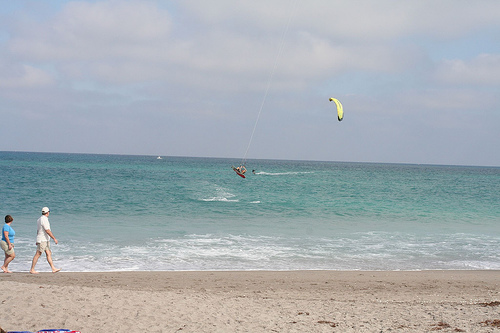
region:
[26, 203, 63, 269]
Man walking on the beach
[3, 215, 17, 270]
Woman walking on the beach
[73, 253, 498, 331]
Sand on a beach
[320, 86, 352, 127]
Kite in the air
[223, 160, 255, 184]
Person kiteboarding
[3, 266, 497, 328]
man and woman walking on sandy beach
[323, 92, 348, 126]
large yellow sail in air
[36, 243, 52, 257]
man wearing khaki shorts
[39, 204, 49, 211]
man wearing white hat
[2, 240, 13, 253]
woman wearing khaki shorts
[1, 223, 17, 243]
woman wearing blue shirt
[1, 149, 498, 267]
blue green water of ocean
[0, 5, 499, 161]
blue sky filled with clouds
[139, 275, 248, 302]
gray sand on the beach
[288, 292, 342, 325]
foot prints on the beach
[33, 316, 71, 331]
edge of blue towel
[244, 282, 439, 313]
thin line on the sand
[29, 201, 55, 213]
white cap on man's head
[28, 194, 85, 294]
man walking on the sand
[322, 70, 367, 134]
large yellow kite over water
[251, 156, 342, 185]
white waves in the water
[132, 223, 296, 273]
waves coming towards the shore line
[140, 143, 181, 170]
white boat in the far distance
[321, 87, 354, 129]
yellow kite on the sky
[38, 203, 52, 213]
man wearing a white hat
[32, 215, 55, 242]
man wearing a white shirt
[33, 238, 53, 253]
man wearing brown shorts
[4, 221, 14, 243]
woman wearing blue shirt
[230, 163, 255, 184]
surfer in the sky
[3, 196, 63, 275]
people walking on the beach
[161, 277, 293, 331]
sand on the ground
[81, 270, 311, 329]
footprints in the sand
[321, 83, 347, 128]
yellow kite in the air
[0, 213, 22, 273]
woman wearing blue shirt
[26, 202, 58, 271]
man wearing white shirt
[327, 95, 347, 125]
yellow and black kite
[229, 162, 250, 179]
kite surfer in the ocean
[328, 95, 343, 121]
yellow sail of a man in the water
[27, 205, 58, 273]
man walking along the edge of the water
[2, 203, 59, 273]
man and woman walking on the beach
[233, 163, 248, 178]
person playing out in the water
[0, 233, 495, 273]
waves crashing on the shore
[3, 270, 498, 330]
sand at the edge of a body of water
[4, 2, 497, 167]
partially cloudy daytime sky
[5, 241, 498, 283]
area where water meets beach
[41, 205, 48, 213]
white hat on a mans head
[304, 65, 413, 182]
A yellow kite in the sky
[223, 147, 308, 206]
A person windsurfing